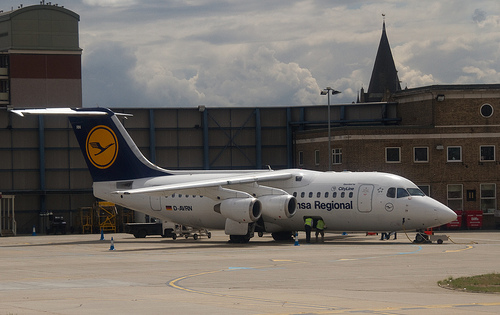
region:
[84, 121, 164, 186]
plane logo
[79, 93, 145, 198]
plane logo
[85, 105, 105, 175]
plane logo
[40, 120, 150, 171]
yellow logo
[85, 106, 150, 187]
yellow logo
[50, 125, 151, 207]
yellow logo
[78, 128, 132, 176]
yellow logo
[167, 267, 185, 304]
the line is yellow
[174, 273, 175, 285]
the line is yellow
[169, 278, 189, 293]
the line is yellow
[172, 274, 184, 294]
the line is yellow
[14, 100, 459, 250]
plane parked on tarmac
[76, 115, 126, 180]
logo on plane tail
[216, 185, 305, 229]
two jet engines under wing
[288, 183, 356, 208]
windows on side of plane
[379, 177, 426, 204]
windshield on plane cockpit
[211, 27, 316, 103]
white clouds in daytime sky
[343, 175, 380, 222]
door on side of plane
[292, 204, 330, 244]
two workers in luggage compartment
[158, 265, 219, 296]
curved yellow line on tarmac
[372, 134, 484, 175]
square windows on building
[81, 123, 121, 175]
The yellow circle on the plane's tail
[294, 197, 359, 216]
The name of the plane's owner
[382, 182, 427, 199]
The windshield of the plane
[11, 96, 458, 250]
The plane on the tarmac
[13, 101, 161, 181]
The tail of the plane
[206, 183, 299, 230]
The engines of the plane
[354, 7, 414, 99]
The steeple in the background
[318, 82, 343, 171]
The light pole beyond the plane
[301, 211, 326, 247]
The men working on the plane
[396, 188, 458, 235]
The nose of the plane